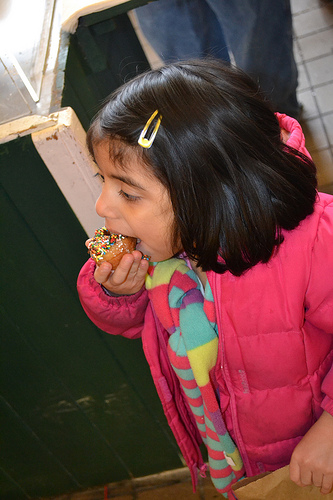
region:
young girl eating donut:
[75, 82, 331, 430]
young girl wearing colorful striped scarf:
[143, 262, 246, 482]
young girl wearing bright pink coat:
[85, 121, 332, 468]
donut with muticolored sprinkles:
[82, 230, 141, 269]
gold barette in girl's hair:
[132, 108, 170, 155]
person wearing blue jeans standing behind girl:
[131, 2, 313, 121]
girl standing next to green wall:
[2, 176, 117, 497]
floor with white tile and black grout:
[274, 4, 330, 160]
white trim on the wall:
[29, 123, 117, 238]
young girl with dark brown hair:
[100, 59, 314, 259]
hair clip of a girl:
[145, 123, 156, 141]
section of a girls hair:
[235, 125, 255, 160]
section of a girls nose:
[102, 191, 111, 206]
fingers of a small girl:
[112, 262, 140, 282]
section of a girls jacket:
[252, 265, 299, 304]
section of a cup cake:
[110, 240, 131, 245]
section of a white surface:
[306, 44, 312, 83]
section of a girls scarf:
[190, 325, 194, 359]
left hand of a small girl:
[307, 426, 324, 464]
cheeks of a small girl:
[150, 216, 160, 232]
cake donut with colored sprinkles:
[86, 222, 142, 270]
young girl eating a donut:
[33, 39, 325, 280]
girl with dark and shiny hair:
[91, 40, 316, 211]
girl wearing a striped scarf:
[145, 259, 258, 494]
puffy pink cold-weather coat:
[63, 249, 332, 492]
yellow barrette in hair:
[109, 94, 196, 166]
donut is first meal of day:
[64, 218, 155, 279]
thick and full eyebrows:
[85, 158, 155, 190]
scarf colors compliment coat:
[152, 263, 247, 489]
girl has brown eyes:
[88, 167, 151, 206]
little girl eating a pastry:
[70, 48, 329, 498]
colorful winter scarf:
[146, 259, 243, 497]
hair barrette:
[128, 104, 169, 156]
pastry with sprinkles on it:
[85, 226, 129, 270]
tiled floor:
[302, 5, 331, 152]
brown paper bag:
[227, 465, 302, 499]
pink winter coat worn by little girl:
[71, 239, 331, 488]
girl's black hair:
[144, 64, 306, 273]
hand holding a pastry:
[81, 221, 149, 300]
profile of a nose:
[89, 174, 117, 227]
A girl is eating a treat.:
[21, 64, 307, 398]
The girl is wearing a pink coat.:
[239, 289, 286, 401]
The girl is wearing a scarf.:
[152, 273, 227, 444]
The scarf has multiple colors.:
[168, 296, 215, 424]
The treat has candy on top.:
[71, 230, 132, 270]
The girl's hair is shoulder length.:
[84, 56, 304, 243]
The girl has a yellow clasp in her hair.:
[126, 90, 172, 155]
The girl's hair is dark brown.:
[103, 64, 288, 258]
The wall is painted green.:
[21, 348, 127, 472]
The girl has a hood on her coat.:
[256, 96, 330, 201]